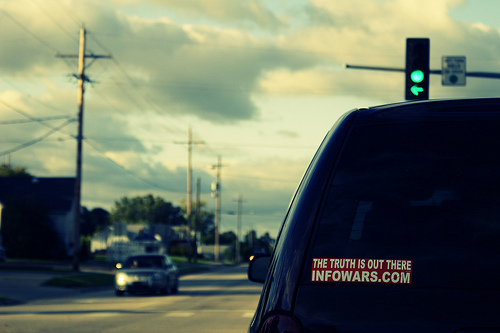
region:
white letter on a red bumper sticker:
[399, 268, 412, 285]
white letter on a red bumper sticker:
[388, 270, 402, 285]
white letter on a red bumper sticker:
[380, 269, 391, 283]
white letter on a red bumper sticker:
[367, 269, 379, 282]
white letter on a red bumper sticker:
[360, 266, 369, 284]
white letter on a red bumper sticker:
[347, 269, 362, 284]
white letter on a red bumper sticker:
[339, 269, 354, 282]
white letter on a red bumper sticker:
[330, 267, 343, 282]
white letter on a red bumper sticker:
[323, 269, 333, 284]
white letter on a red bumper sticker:
[315, 268, 324, 283]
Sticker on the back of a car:
[311, 256, 413, 286]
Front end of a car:
[112, 251, 182, 296]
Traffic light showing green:
[406, 36, 429, 98]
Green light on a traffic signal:
[411, 68, 424, 82]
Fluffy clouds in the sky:
[2, 2, 497, 230]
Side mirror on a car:
[244, 252, 273, 279]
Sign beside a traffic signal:
[440, 52, 469, 87]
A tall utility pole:
[56, 28, 110, 273]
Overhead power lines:
[2, 1, 152, 109]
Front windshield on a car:
[121, 253, 168, 270]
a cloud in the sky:
[171, 40, 236, 106]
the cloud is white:
[168, 47, 247, 111]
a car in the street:
[118, 252, 179, 296]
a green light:
[404, 66, 427, 85]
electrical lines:
[36, 7, 53, 48]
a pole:
[184, 161, 194, 196]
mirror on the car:
[248, 254, 263, 281]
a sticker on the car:
[309, 255, 414, 281]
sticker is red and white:
[306, 254, 410, 287]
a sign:
[439, 55, 469, 87]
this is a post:
[52, 26, 108, 273]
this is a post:
[175, 120, 200, 265]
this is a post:
[209, 151, 227, 273]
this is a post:
[230, 190, 252, 272]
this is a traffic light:
[403, 36, 431, 102]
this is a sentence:
[310, 255, 410, 285]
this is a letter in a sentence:
[330, 270, 336, 280]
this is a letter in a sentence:
[316, 268, 325, 282]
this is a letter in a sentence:
[383, 269, 389, 284]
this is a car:
[113, 250, 185, 292]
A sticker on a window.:
[308, 254, 413, 286]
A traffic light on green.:
[403, 35, 431, 101]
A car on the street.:
[112, 251, 179, 296]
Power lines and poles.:
[3, 0, 256, 266]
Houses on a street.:
[2, 175, 269, 264]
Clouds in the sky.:
[2, 2, 495, 241]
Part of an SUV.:
[245, 93, 499, 331]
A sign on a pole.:
[440, 55, 467, 88]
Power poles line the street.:
[53, 23, 248, 275]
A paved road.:
[2, 260, 263, 331]